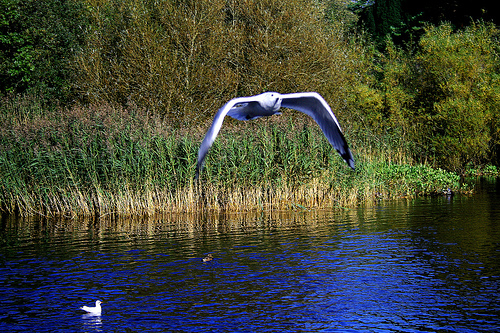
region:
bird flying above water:
[186, 79, 359, 186]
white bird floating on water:
[72, 292, 112, 327]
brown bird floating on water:
[195, 249, 220, 268]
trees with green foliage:
[3, 22, 496, 89]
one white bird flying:
[188, 81, 364, 183]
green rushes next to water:
[16, 106, 428, 233]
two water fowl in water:
[44, 240, 254, 327]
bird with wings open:
[184, 78, 365, 191]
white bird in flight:
[190, 80, 358, 185]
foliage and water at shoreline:
[10, 115, 181, 292]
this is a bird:
[200, 72, 368, 184]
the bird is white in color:
[268, 91, 293, 103]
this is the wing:
[188, 103, 243, 143]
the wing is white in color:
[212, 102, 229, 119]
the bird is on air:
[191, 59, 383, 199]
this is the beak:
[99, 299, 104, 306]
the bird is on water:
[77, 300, 105, 325]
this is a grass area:
[53, 122, 111, 182]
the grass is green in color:
[119, 147, 160, 179]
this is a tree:
[48, 17, 84, 74]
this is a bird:
[189, 71, 364, 183]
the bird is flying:
[194, 72, 363, 171]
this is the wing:
[196, 88, 248, 158]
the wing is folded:
[193, 87, 249, 168]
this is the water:
[242, 235, 406, 323]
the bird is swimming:
[74, 295, 114, 320]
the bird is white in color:
[236, 83, 303, 123]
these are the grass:
[237, 139, 307, 187]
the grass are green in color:
[84, 137, 161, 182]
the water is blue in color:
[270, 232, 387, 326]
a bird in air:
[198, 82, 418, 221]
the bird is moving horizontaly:
[191, 71, 385, 168]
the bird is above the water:
[167, 53, 346, 175]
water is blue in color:
[273, 274, 350, 329]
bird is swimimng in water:
[48, 284, 120, 317]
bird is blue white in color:
[201, 64, 375, 185]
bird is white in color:
[75, 282, 111, 330]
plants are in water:
[101, 146, 182, 213]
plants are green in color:
[86, 129, 154, 159]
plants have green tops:
[79, 108, 178, 143]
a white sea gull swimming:
[45, 180, 134, 331]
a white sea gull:
[64, 283, 134, 329]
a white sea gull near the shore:
[57, 178, 131, 330]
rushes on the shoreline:
[13, 88, 190, 254]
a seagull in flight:
[162, 64, 416, 221]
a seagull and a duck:
[61, 238, 275, 330]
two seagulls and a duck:
[57, 54, 382, 329]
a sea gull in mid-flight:
[160, 56, 395, 243]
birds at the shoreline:
[55, 83, 478, 330]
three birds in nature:
[37, 49, 449, 331]